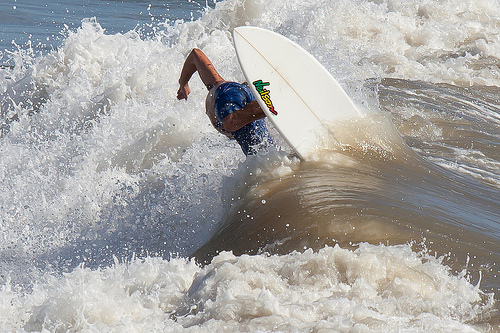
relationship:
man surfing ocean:
[177, 48, 275, 157] [1, 1, 497, 329]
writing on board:
[250, 76, 282, 116] [230, 22, 372, 170]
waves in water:
[45, 65, 165, 231] [2, 4, 499, 331]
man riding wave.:
[177, 48, 275, 157] [2, 2, 495, 330]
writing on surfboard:
[251, 79, 279, 116] [218, 21, 401, 186]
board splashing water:
[230, 25, 365, 161] [2, 4, 499, 331]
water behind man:
[51, 127, 496, 265] [155, 50, 330, 162]